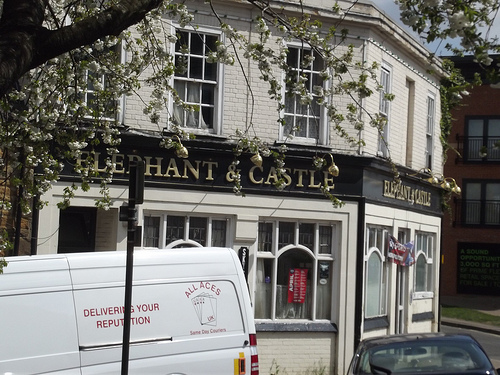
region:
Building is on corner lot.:
[37, 0, 454, 373]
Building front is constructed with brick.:
[28, 1, 458, 373]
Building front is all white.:
[25, 0, 465, 373]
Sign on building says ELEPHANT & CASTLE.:
[43, 132, 449, 217]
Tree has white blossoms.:
[1, 2, 478, 205]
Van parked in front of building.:
[1, 247, 266, 374]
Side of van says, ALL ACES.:
[176, 277, 235, 339]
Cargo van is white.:
[1, 246, 266, 373]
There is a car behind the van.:
[337, 320, 499, 372]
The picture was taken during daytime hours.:
[0, 0, 499, 374]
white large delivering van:
[8, 245, 300, 373]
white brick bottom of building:
[260, 342, 329, 371]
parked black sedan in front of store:
[354, 321, 494, 369]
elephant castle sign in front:
[61, 127, 377, 190]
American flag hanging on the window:
[375, 237, 446, 284]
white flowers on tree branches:
[45, 64, 408, 178]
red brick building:
[459, 85, 499, 320]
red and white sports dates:
[275, 251, 319, 329]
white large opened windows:
[133, 36, 359, 139]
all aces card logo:
[181, 278, 237, 339]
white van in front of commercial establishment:
[40, 228, 263, 368]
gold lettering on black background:
[45, 131, 365, 196]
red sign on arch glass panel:
[265, 237, 320, 313]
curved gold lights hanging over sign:
[400, 165, 465, 196]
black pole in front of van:
[101, 136, 147, 366]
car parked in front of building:
[310, 307, 485, 363]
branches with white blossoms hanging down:
[45, 11, 415, 197]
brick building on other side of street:
[420, 51, 490, 336]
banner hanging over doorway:
[371, 230, 421, 267]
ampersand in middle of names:
[216, 155, 247, 188]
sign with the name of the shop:
[1, 125, 455, 205]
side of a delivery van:
[5, 244, 261, 374]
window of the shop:
[257, 215, 337, 322]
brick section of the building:
[221, 80, 279, 140]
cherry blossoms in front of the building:
[3, 77, 372, 237]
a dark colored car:
[349, 332, 496, 372]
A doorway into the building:
[56, 205, 119, 251]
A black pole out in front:
[118, 125, 160, 374]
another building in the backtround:
[449, 86, 496, 311]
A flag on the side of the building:
[383, 230, 415, 266]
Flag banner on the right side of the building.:
[384, 227, 416, 269]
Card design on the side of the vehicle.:
[186, 292, 227, 332]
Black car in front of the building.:
[333, 325, 490, 374]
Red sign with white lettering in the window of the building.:
[288, 266, 308, 304]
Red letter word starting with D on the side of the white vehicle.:
[80, 306, 136, 315]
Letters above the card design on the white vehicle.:
[177, 274, 228, 299]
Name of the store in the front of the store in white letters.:
[68, 143, 348, 192]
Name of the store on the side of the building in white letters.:
[379, 171, 440, 210]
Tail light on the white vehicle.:
[247, 332, 262, 372]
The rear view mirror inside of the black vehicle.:
[399, 345, 429, 355]